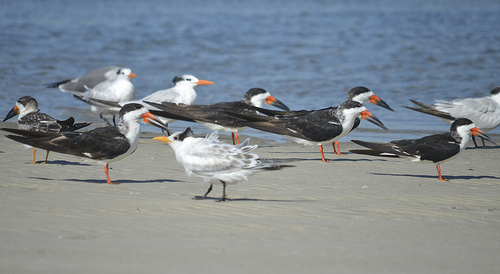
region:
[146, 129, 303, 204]
white bird with yellow beak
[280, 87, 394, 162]
two black birds with orange and black beaks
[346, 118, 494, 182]
a lone black bird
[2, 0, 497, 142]
the ocean behind the birds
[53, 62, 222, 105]
a couple of gulls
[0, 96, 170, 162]
two birds facing opposite directions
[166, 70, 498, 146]
birds marching to the right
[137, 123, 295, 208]
a bird on the sand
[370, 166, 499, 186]
shadow of a bird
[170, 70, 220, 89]
the head of a bird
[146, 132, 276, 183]
the bird is white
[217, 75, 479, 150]
the birds are black and white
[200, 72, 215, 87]
the beak is orange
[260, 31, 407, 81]
the water is blue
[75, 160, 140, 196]
the feet are orange in color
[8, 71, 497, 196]
the birds are eleven in total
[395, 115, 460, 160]
the wings are black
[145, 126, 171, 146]
the beak is yellow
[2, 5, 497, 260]
it is daytime in the photo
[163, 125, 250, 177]
the bird is the smallest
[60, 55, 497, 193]
adult shore birds facing into the wind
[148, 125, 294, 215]
a baby shore bird with ruffled feathers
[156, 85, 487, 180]
adult birds have dark wings and caps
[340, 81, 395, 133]
the birds have orange and black beaks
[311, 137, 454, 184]
the birds have orange legs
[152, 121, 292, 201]
the baby bird has black legs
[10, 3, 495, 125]
the ocean has a rough chop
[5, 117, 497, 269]
the sand on the beach is smooth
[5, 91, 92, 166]
juvenile bird is getting darker wing feathers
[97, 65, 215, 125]
the female birds are white with a black half cap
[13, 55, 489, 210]
birds standing on the shore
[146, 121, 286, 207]
birds with yellow beak and black eye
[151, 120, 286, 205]
bird with white feathers and grey highlights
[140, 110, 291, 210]
bird with dark legs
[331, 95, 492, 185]
bird with black feathers on head like a helment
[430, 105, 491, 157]
bird with long orange and black beak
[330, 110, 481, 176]
bird with white feathers on neck and part of head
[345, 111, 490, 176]
bird with black feathers on body and white highlights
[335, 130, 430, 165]
bird with long black tail feathers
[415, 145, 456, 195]
bird with orange legs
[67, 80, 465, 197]
birds standing in sand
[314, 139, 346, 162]
orange legs of birds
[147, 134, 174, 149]
yellow beak of bird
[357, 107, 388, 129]
orange and black beak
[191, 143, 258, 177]
wing of bird facing left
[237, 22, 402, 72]
blue choppy water in background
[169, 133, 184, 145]
black eye of bird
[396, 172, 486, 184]
shadow of bird in sand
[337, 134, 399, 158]
black tail of bird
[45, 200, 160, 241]
gray smooth beach sand